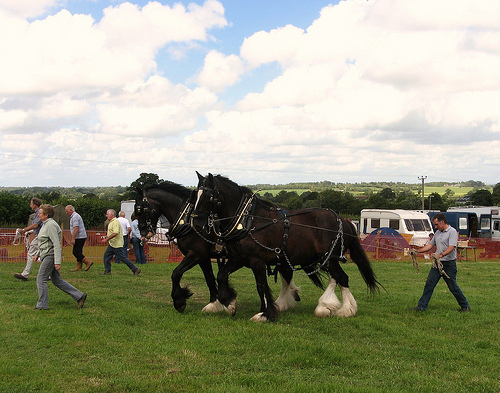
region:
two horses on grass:
[130, 171, 385, 334]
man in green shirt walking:
[31, 203, 88, 310]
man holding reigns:
[419, 211, 471, 326]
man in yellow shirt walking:
[102, 208, 134, 291]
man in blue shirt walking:
[65, 199, 92, 274]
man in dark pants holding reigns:
[416, 213, 473, 330]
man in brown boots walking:
[61, 202, 94, 273]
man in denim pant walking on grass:
[100, 208, 143, 284]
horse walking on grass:
[186, 172, 383, 334]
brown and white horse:
[189, 173, 376, 322]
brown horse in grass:
[124, 180, 219, 312]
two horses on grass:
[129, 176, 376, 317]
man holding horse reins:
[418, 215, 472, 314]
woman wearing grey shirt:
[33, 206, 87, 311]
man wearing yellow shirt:
[101, 209, 139, 279]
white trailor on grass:
[360, 206, 432, 248]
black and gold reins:
[218, 186, 258, 242]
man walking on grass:
[63, 203, 95, 273]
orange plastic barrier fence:
[1, 228, 498, 261]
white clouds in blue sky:
[5, 22, 89, 83]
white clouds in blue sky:
[20, 102, 104, 147]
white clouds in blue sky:
[108, 19, 196, 76]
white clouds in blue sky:
[185, 3, 249, 54]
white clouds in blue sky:
[245, 15, 345, 75]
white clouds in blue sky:
[265, 70, 401, 115]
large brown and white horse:
[180, 165, 380, 321]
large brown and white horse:
[110, 168, 190, 301]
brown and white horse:
[115, 175, 187, 295]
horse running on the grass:
[131, 172, 378, 321]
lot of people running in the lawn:
[24, 195, 141, 322]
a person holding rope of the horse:
[291, 213, 464, 269]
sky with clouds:
[146, 62, 420, 162]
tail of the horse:
[347, 232, 388, 295]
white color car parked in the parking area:
[358, 202, 430, 247]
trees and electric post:
[318, 180, 450, 205]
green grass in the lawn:
[122, 311, 358, 381]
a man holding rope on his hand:
[411, 213, 468, 320]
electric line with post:
[403, 166, 446, 201]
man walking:
[25, 204, 92, 315]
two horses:
[118, 168, 373, 324]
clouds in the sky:
[272, 17, 486, 137]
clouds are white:
[252, 24, 477, 135]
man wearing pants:
[420, 266, 470, 311]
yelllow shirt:
[107, 224, 125, 248]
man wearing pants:
[70, 239, 86, 260]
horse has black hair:
[161, 178, 195, 195]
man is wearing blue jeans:
[104, 248, 139, 272]